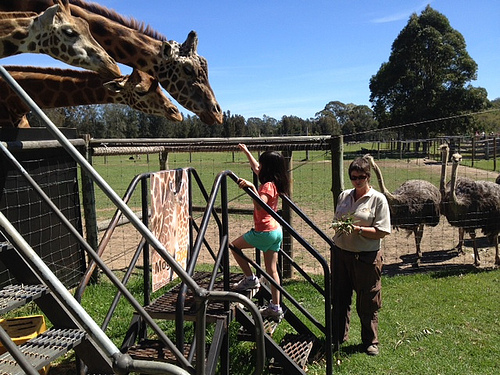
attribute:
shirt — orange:
[253, 181, 278, 231]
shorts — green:
[228, 225, 310, 257]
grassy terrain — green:
[92, 134, 499, 373]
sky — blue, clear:
[1, 0, 497, 130]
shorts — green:
[239, 221, 286, 256]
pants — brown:
[320, 239, 387, 347]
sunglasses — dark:
[349, 170, 371, 181]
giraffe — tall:
[4, 0, 222, 128]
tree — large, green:
[367, 3, 489, 153]